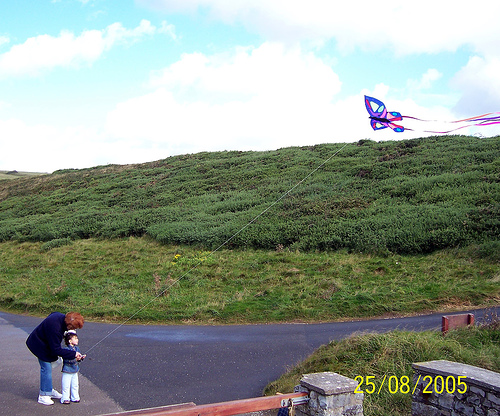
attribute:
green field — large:
[36, 137, 433, 237]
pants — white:
[53, 373, 83, 407]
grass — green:
[93, 173, 426, 279]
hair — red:
[65, 306, 84, 330]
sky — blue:
[103, 71, 129, 89]